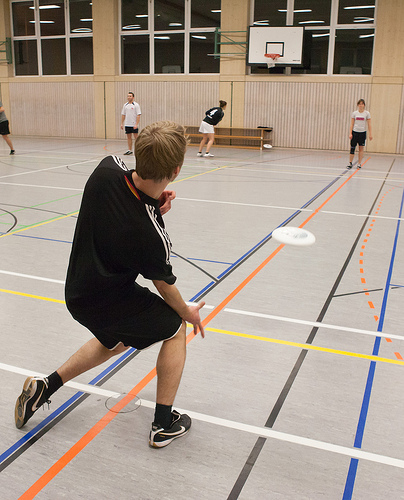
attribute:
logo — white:
[158, 425, 188, 435]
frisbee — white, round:
[273, 224, 317, 247]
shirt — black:
[67, 154, 175, 316]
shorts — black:
[63, 283, 178, 350]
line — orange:
[188, 156, 379, 343]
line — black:
[248, 157, 391, 459]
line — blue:
[331, 192, 402, 477]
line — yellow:
[2, 275, 402, 371]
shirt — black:
[203, 107, 224, 124]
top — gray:
[352, 111, 370, 132]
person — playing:
[13, 122, 318, 446]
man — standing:
[118, 92, 143, 156]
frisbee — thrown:
[260, 144, 274, 152]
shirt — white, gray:
[349, 109, 372, 138]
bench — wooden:
[183, 125, 272, 148]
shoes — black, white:
[16, 374, 192, 448]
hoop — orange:
[263, 50, 279, 67]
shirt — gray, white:
[123, 104, 142, 131]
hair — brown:
[135, 121, 186, 181]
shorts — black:
[351, 133, 367, 146]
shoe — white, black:
[150, 414, 194, 449]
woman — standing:
[350, 101, 374, 168]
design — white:
[208, 108, 217, 117]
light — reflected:
[136, 13, 149, 18]